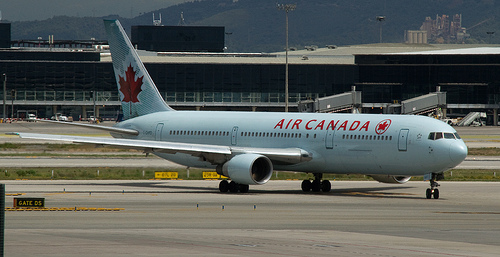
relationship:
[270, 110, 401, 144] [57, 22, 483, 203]
logo on airplane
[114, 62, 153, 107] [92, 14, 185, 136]
leaf on tail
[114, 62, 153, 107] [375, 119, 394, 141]
leaf in circle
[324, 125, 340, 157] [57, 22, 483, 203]
door on plane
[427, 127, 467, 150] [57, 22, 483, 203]
windows on airplane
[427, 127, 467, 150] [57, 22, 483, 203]
winshield on airplane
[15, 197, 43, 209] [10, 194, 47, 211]
black yellow sign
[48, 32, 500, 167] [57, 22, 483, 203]
buildings behind airplane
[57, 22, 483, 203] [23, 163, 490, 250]
airplane on ground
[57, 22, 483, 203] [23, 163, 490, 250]
airplane on runway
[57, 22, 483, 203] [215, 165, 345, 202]
airplane has wheels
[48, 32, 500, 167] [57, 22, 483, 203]
buildings behind plane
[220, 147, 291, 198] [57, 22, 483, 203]
engine on plane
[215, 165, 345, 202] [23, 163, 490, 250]
wheels on ground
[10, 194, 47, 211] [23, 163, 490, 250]
sign on road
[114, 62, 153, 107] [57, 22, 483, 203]
leaf on airplane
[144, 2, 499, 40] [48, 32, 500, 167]
mountains behind buildings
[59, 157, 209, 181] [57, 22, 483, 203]
grass behind airplane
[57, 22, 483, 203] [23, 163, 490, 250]
airplane on tarmac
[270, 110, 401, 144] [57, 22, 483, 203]
logo on plane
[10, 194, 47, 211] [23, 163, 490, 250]
sign on ground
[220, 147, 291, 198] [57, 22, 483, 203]
engines on airplane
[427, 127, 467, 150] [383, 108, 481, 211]
windows on front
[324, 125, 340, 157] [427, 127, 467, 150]
door by windows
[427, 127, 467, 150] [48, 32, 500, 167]
windows on buildings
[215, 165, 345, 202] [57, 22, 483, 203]
wheels on airplane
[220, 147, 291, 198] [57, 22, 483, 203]
engine on airplane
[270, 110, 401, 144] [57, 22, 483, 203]
words on airplane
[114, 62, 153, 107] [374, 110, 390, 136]
leaf inside cirl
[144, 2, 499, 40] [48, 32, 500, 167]
mountains behind buildingz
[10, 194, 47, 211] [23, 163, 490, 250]
sign on runway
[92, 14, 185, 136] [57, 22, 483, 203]
tail of airplane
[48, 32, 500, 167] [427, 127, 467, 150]
buildings with windows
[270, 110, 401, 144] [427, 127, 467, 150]
words above windows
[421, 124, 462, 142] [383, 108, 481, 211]
winshield on front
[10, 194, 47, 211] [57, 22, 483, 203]
sign by airplane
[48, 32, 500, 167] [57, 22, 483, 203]
terminal behind airplane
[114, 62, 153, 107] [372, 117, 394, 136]
leaf in circle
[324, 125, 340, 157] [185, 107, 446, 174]
door on side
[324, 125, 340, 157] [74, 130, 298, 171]
door by wing